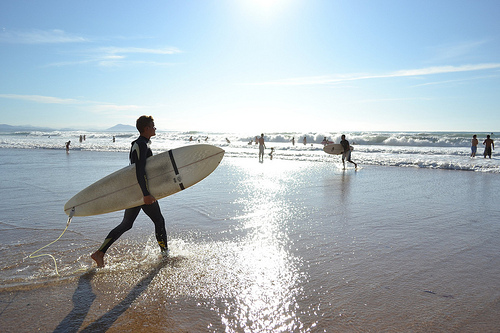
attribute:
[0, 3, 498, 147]
sky — blue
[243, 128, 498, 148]
wave — crashing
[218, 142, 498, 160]
wave — crashing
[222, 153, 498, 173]
wave — crashing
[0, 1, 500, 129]
sky — bright, blue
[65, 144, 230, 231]
surfboard — white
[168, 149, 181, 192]
strip — black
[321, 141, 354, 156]
surfboard — white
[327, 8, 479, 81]
sky — blue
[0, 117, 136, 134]
mountains — hazy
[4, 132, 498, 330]
water — splashed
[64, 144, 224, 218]
surfboard — white, long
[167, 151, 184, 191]
stripe — black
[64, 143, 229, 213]
surfboard — white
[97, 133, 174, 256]
wetsuit — blue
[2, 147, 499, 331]
sand — watery